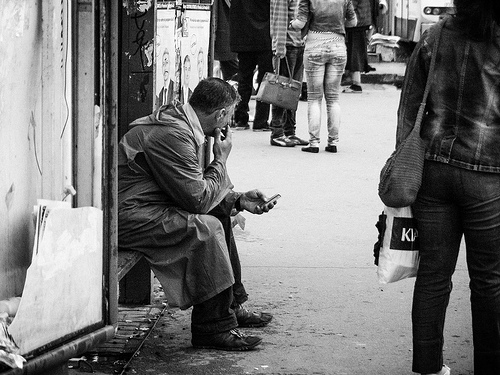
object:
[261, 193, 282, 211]
cell phone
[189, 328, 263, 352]
shoe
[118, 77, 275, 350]
man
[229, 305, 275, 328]
shoe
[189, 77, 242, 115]
hair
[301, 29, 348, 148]
jeans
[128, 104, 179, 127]
hood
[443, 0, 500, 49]
hair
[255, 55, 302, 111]
bag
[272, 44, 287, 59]
woman's hand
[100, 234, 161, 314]
stoop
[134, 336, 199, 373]
shadow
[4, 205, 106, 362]
broken area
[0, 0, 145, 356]
truck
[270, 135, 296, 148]
sneakers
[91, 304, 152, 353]
floor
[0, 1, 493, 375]
street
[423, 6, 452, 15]
sign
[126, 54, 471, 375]
road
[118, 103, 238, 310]
coat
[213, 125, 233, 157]
hand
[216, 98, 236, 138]
face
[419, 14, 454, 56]
shoulder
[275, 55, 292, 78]
handle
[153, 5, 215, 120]
wall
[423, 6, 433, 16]
lights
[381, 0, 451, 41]
vehicle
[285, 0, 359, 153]
people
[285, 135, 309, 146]
sneakers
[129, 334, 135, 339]
cigarette butts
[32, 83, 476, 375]
ground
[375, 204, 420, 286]
bag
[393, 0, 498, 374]
girl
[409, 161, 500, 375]
jeans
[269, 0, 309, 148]
man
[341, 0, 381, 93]
woman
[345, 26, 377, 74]
skirt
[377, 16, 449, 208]
bag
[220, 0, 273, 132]
man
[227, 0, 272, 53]
clothes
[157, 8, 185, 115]
door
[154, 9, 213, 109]
poster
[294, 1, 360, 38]
top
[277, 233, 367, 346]
sidewalk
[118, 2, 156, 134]
wall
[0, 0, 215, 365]
building